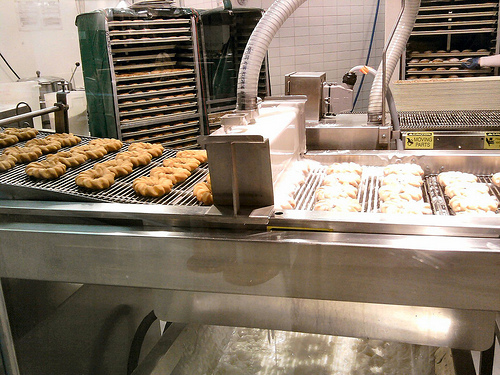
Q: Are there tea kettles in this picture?
A: No, there are no tea kettles.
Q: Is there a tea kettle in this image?
A: No, there are no tea kettles.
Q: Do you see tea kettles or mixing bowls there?
A: No, there are no tea kettles or mixing bowls.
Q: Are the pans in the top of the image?
A: Yes, the pans are in the top of the image.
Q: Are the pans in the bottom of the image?
A: No, the pans are in the top of the image.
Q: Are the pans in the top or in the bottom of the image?
A: The pans are in the top of the image.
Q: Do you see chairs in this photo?
A: No, there are no chairs.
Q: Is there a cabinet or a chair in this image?
A: No, there are no chairs or cabinets.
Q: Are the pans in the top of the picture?
A: Yes, the pans are in the top of the image.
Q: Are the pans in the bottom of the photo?
A: No, the pans are in the top of the image.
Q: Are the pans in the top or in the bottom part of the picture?
A: The pans are in the top of the image.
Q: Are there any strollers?
A: No, there are no strollers.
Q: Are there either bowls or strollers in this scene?
A: No, there are no strollers or bowls.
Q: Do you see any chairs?
A: No, there are no chairs.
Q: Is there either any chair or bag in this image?
A: No, there are no chairs or bags.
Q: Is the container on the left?
A: Yes, the container is on the left of the image.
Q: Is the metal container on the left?
A: Yes, the container is on the left of the image.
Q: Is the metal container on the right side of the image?
A: No, the container is on the left of the image.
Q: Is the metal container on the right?
A: No, the container is on the left of the image.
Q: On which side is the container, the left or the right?
A: The container is on the left of the image.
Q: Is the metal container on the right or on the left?
A: The container is on the left of the image.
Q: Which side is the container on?
A: The container is on the left of the image.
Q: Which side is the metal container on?
A: The container is on the left of the image.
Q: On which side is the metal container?
A: The container is on the left of the image.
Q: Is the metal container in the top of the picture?
A: Yes, the container is in the top of the image.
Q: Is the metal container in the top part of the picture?
A: Yes, the container is in the top of the image.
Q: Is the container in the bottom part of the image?
A: No, the container is in the top of the image.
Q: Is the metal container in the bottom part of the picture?
A: No, the container is in the top of the image.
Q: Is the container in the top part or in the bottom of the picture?
A: The container is in the top of the image.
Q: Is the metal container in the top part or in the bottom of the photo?
A: The container is in the top of the image.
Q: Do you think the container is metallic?
A: Yes, the container is metallic.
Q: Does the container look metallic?
A: Yes, the container is metallic.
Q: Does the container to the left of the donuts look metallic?
A: Yes, the container is metallic.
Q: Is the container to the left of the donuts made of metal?
A: Yes, the container is made of metal.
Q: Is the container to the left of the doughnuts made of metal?
A: Yes, the container is made of metal.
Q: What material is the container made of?
A: The container is made of metal.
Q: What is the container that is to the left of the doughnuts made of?
A: The container is made of metal.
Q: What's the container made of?
A: The container is made of metal.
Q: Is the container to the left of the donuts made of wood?
A: No, the container is made of metal.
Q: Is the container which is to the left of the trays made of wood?
A: No, the container is made of metal.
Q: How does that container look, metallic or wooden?
A: The container is metallic.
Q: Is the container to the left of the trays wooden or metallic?
A: The container is metallic.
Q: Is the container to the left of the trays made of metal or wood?
A: The container is made of metal.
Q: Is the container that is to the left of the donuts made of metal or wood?
A: The container is made of metal.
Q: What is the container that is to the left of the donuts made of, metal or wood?
A: The container is made of metal.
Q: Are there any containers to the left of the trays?
A: Yes, there is a container to the left of the trays.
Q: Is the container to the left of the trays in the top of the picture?
A: Yes, the container is to the left of the trays.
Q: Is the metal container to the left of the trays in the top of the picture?
A: Yes, the container is to the left of the trays.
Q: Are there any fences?
A: No, there are no fences.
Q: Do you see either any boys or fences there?
A: No, there are no fences or boys.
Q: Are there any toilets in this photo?
A: No, there are no toilets.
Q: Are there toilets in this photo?
A: No, there are no toilets.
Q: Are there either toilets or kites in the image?
A: No, there are no toilets or kites.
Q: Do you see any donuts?
A: Yes, there are donuts.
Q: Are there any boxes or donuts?
A: Yes, there are donuts.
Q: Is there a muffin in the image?
A: No, there are no muffins.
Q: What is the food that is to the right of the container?
A: The food is donuts.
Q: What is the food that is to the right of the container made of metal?
A: The food is donuts.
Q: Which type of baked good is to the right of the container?
A: The food is donuts.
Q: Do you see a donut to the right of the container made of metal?
A: Yes, there are donuts to the right of the container.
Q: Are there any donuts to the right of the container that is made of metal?
A: Yes, there are donuts to the right of the container.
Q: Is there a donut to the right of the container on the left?
A: Yes, there are donuts to the right of the container.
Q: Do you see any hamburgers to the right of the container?
A: No, there are donuts to the right of the container.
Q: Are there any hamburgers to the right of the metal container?
A: No, there are donuts to the right of the container.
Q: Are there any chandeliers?
A: No, there are no chandeliers.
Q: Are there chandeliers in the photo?
A: No, there are no chandeliers.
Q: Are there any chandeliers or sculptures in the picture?
A: No, there are no chandeliers or sculptures.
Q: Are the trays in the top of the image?
A: Yes, the trays are in the top of the image.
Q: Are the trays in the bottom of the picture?
A: No, the trays are in the top of the image.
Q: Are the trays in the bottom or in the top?
A: The trays are in the top of the image.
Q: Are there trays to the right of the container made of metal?
A: Yes, there are trays to the right of the container.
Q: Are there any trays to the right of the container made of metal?
A: Yes, there are trays to the right of the container.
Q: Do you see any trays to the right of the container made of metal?
A: Yes, there are trays to the right of the container.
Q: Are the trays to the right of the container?
A: Yes, the trays are to the right of the container.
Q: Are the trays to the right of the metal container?
A: Yes, the trays are to the right of the container.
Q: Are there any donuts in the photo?
A: Yes, there is a donut.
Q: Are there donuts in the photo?
A: Yes, there is a donut.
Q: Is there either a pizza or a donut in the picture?
A: Yes, there is a donut.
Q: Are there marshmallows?
A: No, there are no marshmallows.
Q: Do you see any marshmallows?
A: No, there are no marshmallows.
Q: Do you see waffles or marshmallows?
A: No, there are no marshmallows or waffles.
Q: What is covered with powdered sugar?
A: The doughnut is covered with powdered sugar.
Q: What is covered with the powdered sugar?
A: The doughnut is covered with powdered sugar.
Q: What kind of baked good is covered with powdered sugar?
A: The food is a donut.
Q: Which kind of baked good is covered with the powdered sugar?
A: The food is a donut.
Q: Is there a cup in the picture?
A: No, there are no cups.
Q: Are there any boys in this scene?
A: No, there are no boys.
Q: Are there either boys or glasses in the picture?
A: No, there are no boys or glasses.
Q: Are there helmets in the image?
A: No, there are no helmets.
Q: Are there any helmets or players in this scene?
A: No, there are no helmets or players.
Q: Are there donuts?
A: Yes, there is a donut.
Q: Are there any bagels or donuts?
A: Yes, there is a donut.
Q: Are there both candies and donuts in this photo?
A: No, there is a donut but no candies.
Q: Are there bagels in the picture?
A: No, there are no bagels.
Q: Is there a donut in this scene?
A: Yes, there are donuts.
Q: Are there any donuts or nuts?
A: Yes, there are donuts.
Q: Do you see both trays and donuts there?
A: Yes, there are both donuts and a tray.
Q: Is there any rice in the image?
A: No, there is no rice.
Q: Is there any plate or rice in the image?
A: No, there are no rice or plates.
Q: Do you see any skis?
A: No, there are no skis.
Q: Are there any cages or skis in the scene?
A: No, there are no skis or cages.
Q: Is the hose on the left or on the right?
A: The hose is on the left of the image.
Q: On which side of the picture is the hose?
A: The hose is on the left of the image.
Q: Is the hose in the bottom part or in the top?
A: The hose is in the bottom of the image.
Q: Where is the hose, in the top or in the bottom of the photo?
A: The hose is in the bottom of the image.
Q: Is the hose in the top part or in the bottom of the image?
A: The hose is in the bottom of the image.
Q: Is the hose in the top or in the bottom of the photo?
A: The hose is in the bottom of the image.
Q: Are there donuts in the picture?
A: Yes, there is a donut.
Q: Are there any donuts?
A: Yes, there is a donut.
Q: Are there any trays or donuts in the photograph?
A: Yes, there is a donut.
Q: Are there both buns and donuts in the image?
A: No, there is a donut but no buns.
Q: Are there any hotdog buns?
A: No, there are no hotdog buns.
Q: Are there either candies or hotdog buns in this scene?
A: No, there are no hotdog buns or candies.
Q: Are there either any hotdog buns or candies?
A: No, there are no hotdog buns or candies.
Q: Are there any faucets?
A: No, there are no faucets.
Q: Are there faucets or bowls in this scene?
A: No, there are no faucets or bowls.